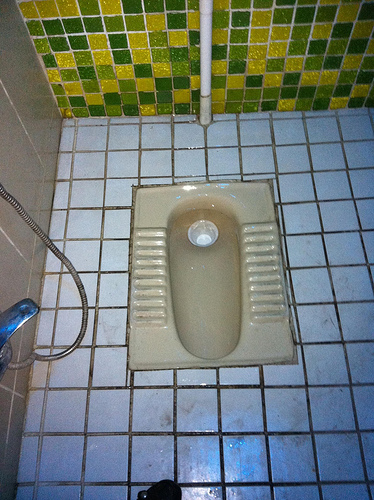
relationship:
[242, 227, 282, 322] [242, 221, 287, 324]
feet has feet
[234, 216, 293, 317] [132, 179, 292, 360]
grooves on toilet